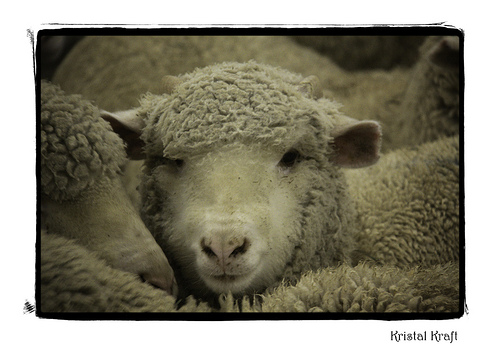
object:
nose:
[197, 228, 252, 269]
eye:
[274, 143, 310, 172]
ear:
[321, 112, 382, 169]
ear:
[100, 107, 148, 143]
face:
[152, 137, 315, 293]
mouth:
[189, 254, 265, 293]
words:
[390, 330, 457, 343]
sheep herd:
[39, 28, 460, 313]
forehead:
[152, 68, 328, 155]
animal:
[100, 60, 382, 309]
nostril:
[222, 236, 253, 263]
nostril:
[196, 235, 223, 264]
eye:
[157, 153, 190, 178]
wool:
[149, 69, 330, 163]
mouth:
[194, 255, 261, 296]